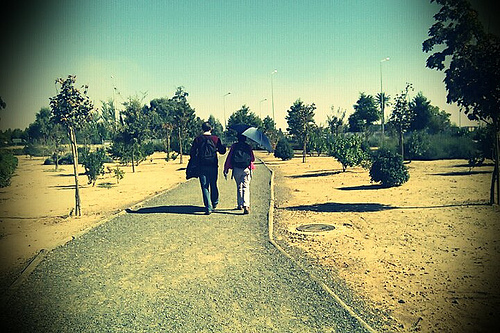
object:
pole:
[373, 66, 392, 164]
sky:
[0, 0, 468, 110]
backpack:
[195, 135, 220, 165]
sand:
[310, 203, 339, 222]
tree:
[423, 1, 497, 204]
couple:
[190, 121, 257, 216]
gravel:
[112, 193, 132, 220]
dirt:
[126, 177, 145, 198]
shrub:
[367, 157, 412, 188]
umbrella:
[228, 122, 274, 156]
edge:
[254, 162, 289, 272]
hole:
[295, 223, 338, 234]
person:
[222, 130, 256, 214]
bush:
[274, 136, 297, 163]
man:
[187, 121, 227, 215]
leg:
[241, 176, 252, 213]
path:
[0, 157, 382, 333]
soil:
[138, 168, 160, 185]